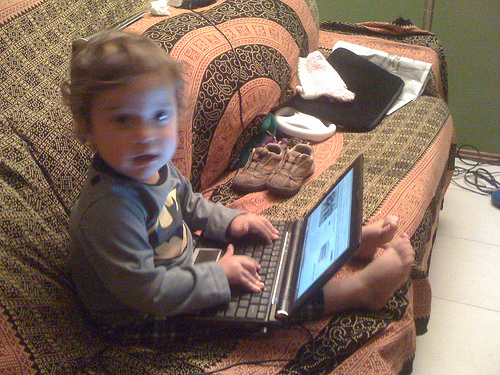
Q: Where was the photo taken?
A: Living Room.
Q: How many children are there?
A: One.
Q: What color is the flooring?
A: White.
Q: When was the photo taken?
A: Night time.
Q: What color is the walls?
A: Green.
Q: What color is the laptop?
A: Black.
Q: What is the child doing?
A: Using the laptop.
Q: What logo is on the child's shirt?
A: Batman.